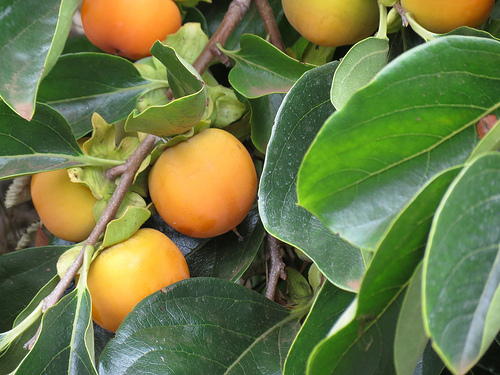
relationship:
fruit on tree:
[147, 128, 259, 241] [1, 1, 500, 374]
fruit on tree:
[30, 171, 113, 243] [1, 1, 500, 374]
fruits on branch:
[30, 124, 257, 334] [86, 0, 262, 247]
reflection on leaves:
[71, 306, 83, 374] [2, 251, 95, 374]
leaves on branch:
[2, 251, 95, 374] [86, 0, 262, 247]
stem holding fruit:
[82, 154, 128, 167] [30, 171, 113, 243]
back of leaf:
[437, 194, 457, 266] [423, 150, 499, 374]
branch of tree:
[86, 0, 262, 247] [1, 1, 500, 374]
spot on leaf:
[475, 112, 497, 139] [297, 34, 500, 251]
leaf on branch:
[297, 34, 500, 251] [86, 0, 262, 247]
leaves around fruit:
[2, 251, 95, 374] [30, 171, 113, 243]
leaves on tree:
[2, 251, 95, 374] [1, 1, 500, 374]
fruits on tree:
[30, 124, 257, 334] [1, 1, 500, 374]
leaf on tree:
[297, 34, 500, 251] [1, 1, 500, 374]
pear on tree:
[400, 0, 496, 34] [1, 1, 500, 374]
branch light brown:
[86, 0, 262, 247] [266, 17, 277, 30]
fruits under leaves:
[30, 124, 257, 334] [2, 251, 95, 374]